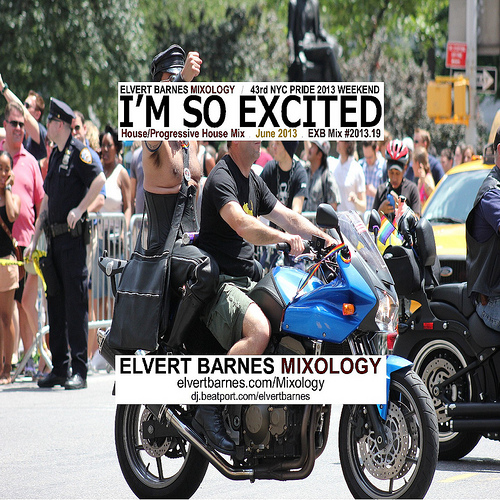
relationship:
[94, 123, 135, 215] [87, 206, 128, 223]
woman behind railing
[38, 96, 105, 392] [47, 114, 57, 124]
officer wearing sunglasses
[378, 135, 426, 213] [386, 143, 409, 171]
man wearing helmet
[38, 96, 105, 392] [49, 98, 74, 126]
officer wearing hat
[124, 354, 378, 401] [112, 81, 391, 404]
details on flyer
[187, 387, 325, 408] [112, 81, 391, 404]
address on flyer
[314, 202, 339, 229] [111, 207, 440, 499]
mirror on bike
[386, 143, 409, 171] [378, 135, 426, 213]
helmet on man